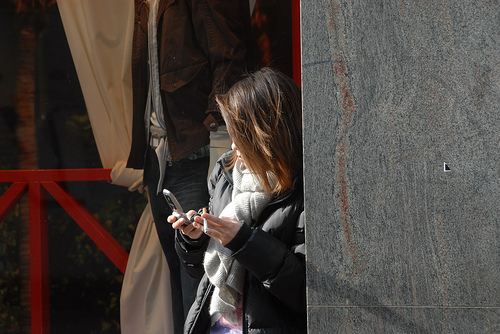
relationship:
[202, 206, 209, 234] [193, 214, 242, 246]
cigarette in left hand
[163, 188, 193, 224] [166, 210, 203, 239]
cell phone in right hand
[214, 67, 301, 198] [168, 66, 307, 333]
hair on woman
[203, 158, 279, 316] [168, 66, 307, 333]
scarf on woman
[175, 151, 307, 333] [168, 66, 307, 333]
coat on woman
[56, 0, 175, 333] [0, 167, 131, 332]
cloth around railing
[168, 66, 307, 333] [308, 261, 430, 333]
woman has shadow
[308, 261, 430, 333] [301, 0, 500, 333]
shadow on wall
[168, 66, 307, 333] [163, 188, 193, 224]
woman looking at her cell phone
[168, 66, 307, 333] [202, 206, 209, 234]
woman smoking a cigarette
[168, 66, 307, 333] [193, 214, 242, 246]
woman has left hand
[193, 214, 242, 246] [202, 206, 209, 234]
left hand holding cigarette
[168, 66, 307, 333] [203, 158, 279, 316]
woman wearing a scarf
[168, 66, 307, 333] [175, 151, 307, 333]
woman wearing a coat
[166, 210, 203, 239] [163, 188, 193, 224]
right hand holding cell phone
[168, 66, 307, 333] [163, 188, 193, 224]
woman holding cell phone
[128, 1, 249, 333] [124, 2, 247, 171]
person wearing jacket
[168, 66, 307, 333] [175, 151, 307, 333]
woman wearing coat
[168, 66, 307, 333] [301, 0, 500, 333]
woman next to a wall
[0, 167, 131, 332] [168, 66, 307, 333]
railing behind woman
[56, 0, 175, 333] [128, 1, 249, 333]
cloth behind person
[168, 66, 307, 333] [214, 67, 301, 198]
woman with hair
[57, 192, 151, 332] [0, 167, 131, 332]
bush behind railing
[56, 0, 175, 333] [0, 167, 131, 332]
cloth next to railing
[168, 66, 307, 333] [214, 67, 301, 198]
woman has hair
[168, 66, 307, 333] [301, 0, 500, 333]
woman leaning against wall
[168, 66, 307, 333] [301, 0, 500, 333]
woman by a wall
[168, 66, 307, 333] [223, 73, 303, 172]
woman has head